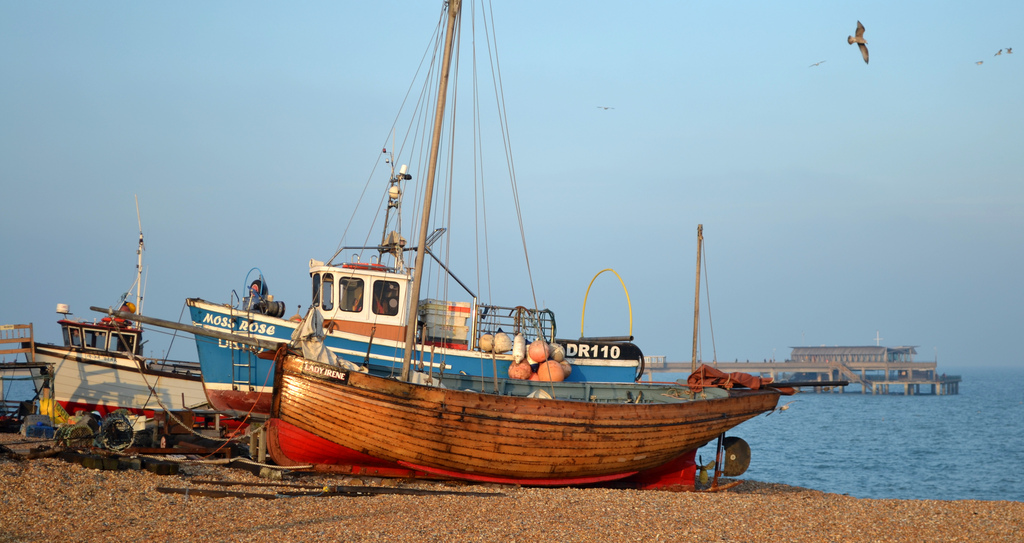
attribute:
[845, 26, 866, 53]
bird — flying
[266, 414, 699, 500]
bottom — red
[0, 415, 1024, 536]
beach — white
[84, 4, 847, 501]
boat — blue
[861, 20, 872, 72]
wings — extended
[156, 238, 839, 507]
boat — wooden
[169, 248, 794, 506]
boat — blue, docked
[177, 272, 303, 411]
boat — docked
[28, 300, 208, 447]
boat — docked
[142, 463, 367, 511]
plank — wood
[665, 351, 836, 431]
cloth — broen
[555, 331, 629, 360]
letters — white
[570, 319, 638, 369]
letters — white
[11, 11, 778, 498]
house — wheel 